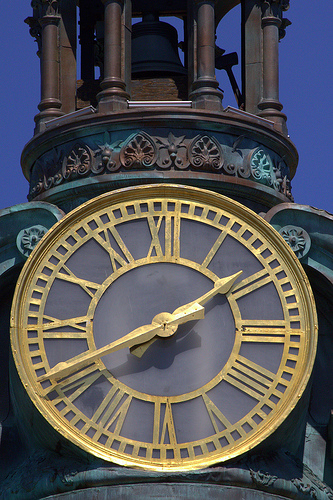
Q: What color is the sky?
A: Blue.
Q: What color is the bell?
A: Black.